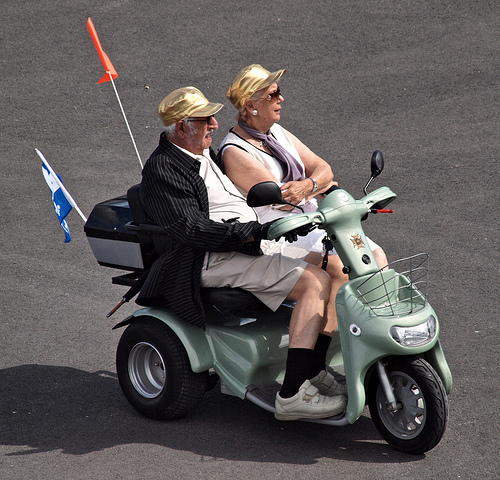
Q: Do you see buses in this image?
A: No, there are no buses.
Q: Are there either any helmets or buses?
A: No, there are no buses or helmets.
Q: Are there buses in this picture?
A: No, there are no buses.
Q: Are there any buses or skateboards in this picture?
A: No, there are no buses or skateboards.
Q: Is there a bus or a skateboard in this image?
A: No, there are no buses or skateboards.